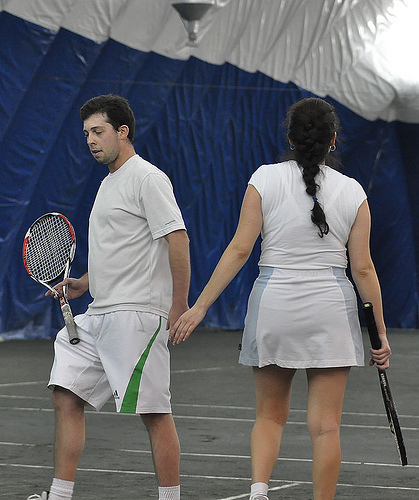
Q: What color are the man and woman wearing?
A: White.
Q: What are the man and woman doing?
A: Playing tennis.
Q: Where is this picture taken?
A: A tennis court.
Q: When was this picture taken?
A: Daytime.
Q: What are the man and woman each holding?
A: Tennis rackets.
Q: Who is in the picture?
A: A man and a woman.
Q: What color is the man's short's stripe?
A: Green.